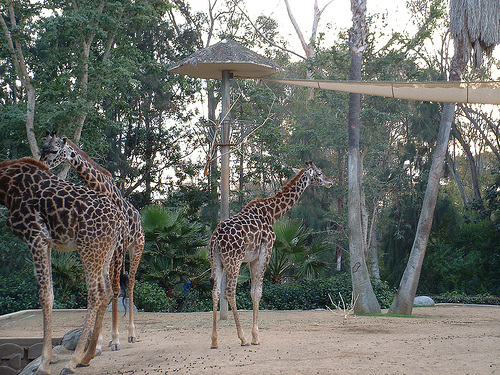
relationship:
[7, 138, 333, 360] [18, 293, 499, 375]
giraffes on ground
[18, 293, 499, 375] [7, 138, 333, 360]
ground under giraffes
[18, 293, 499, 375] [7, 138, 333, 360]
ground below giraffes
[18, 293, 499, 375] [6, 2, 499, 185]
ground under sky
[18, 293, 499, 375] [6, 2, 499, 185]
ground below sky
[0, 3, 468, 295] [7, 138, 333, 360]
trees behind giraffes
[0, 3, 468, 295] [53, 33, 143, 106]
trees with leaves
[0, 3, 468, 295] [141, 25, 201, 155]
trees with leaves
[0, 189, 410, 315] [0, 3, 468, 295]
bushes with trees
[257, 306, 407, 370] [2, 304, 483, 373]
dirt in enclosure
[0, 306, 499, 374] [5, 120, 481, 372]
dirt in enclosure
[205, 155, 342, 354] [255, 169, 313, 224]
giraffe has neck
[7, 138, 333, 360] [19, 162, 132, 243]
giraffes has spots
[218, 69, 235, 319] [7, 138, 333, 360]
beam stands above giraffes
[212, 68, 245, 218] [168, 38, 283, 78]
pole supporting lid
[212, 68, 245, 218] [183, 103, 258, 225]
pole supporting basket